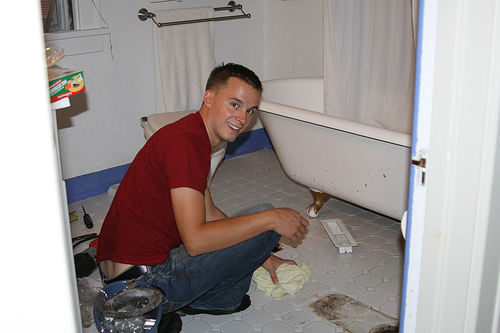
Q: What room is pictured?
A: It is a bathroom.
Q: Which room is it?
A: It is a bathroom.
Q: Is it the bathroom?
A: Yes, it is the bathroom.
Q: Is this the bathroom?
A: Yes, it is the bathroom.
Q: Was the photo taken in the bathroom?
A: Yes, it was taken in the bathroom.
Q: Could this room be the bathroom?
A: Yes, it is the bathroom.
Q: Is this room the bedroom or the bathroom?
A: It is the bathroom.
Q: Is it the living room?
A: No, it is the bathroom.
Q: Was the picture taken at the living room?
A: No, the picture was taken in the bathroom.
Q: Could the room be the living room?
A: No, it is the bathroom.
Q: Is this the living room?
A: No, it is the bathroom.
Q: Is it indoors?
A: Yes, it is indoors.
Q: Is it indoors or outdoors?
A: It is indoors.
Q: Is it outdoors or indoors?
A: It is indoors.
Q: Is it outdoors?
A: No, it is indoors.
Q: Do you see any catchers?
A: No, there are no catchers.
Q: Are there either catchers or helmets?
A: No, there are no catchers or helmets.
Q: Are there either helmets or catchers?
A: No, there are no catchers or helmets.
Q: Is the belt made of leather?
A: Yes, the belt is made of leather.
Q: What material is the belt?
A: The belt is made of leather.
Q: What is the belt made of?
A: The belt is made of leather.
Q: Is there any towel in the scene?
A: Yes, there is a towel.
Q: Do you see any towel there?
A: Yes, there is a towel.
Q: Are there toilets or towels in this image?
A: Yes, there is a towel.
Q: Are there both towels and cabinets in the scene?
A: No, there is a towel but no cabinets.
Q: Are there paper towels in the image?
A: No, there are no paper towels.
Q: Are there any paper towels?
A: No, there are no paper towels.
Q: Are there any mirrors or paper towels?
A: No, there are no paper towels or mirrors.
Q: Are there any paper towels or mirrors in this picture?
A: No, there are no paper towels or mirrors.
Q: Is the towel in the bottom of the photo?
A: Yes, the towel is in the bottom of the image.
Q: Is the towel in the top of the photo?
A: No, the towel is in the bottom of the image.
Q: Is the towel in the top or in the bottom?
A: The towel is in the bottom of the image.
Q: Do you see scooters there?
A: No, there are no scooters.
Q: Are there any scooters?
A: No, there are no scooters.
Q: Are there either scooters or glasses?
A: No, there are no scooters or glasses.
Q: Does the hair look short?
A: Yes, the hair is short.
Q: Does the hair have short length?
A: Yes, the hair is short.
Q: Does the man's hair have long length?
A: No, the hair is short.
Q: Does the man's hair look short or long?
A: The hair is short.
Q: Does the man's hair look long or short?
A: The hair is short.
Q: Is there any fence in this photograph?
A: No, there are no fences.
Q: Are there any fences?
A: No, there are no fences.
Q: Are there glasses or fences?
A: No, there are no fences or glasses.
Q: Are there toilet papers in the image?
A: No, there are no toilet papers.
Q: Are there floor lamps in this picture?
A: No, there are no floor lamps.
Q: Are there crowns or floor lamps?
A: No, there are no floor lamps or crowns.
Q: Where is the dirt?
A: The dirt is on the floor.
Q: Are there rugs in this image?
A: No, there are no rugs.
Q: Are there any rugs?
A: No, there are no rugs.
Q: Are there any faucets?
A: No, there are no faucets.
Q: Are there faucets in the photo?
A: No, there are no faucets.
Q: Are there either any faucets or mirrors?
A: No, there are no faucets or mirrors.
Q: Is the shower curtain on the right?
A: Yes, the shower curtain is on the right of the image.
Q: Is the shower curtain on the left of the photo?
A: No, the shower curtain is on the right of the image.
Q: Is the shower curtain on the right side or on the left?
A: The shower curtain is on the right of the image.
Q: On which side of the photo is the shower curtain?
A: The shower curtain is on the right of the image.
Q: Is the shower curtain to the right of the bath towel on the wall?
A: Yes, the shower curtain is to the right of the bath towel.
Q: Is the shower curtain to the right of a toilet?
A: No, the shower curtain is to the right of the bath towel.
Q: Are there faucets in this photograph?
A: No, there are no faucets.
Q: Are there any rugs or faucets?
A: No, there are no faucets or rugs.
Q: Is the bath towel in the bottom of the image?
A: No, the bath towel is in the top of the image.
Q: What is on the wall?
A: The bath towel is on the wall.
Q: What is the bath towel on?
A: The bath towel is on the wall.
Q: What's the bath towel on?
A: The bath towel is on the wall.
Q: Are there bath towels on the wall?
A: Yes, there is a bath towel on the wall.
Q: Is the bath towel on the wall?
A: Yes, the bath towel is on the wall.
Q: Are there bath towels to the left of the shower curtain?
A: Yes, there is a bath towel to the left of the shower curtain.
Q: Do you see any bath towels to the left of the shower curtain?
A: Yes, there is a bath towel to the left of the shower curtain.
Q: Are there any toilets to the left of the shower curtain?
A: No, there is a bath towel to the left of the shower curtain.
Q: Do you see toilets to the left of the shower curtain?
A: No, there is a bath towel to the left of the shower curtain.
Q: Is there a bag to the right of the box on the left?
A: No, there is a bath towel to the right of the box.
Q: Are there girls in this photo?
A: No, there are no girls.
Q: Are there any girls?
A: No, there are no girls.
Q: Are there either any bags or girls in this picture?
A: No, there are no girls or bags.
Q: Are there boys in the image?
A: No, there are no boys.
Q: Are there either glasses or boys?
A: No, there are no boys or glasses.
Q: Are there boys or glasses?
A: No, there are no boys or glasses.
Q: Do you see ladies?
A: No, there are no ladies.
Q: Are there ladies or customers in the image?
A: No, there are no ladies or customers.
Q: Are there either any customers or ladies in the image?
A: No, there are no ladies or customers.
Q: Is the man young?
A: Yes, the man is young.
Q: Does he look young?
A: Yes, the man is young.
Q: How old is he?
A: The man is young.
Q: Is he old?
A: No, the man is young.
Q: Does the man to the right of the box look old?
A: No, the man is young.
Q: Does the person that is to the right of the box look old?
A: No, the man is young.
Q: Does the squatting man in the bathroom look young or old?
A: The man is young.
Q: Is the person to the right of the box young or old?
A: The man is young.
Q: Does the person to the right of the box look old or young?
A: The man is young.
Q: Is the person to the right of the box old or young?
A: The man is young.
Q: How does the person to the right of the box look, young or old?
A: The man is young.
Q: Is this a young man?
A: Yes, this is a young man.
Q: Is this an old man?
A: No, this is a young man.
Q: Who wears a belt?
A: The man wears a belt.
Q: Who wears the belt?
A: The man wears a belt.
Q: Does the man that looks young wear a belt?
A: Yes, the man wears a belt.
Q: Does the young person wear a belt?
A: Yes, the man wears a belt.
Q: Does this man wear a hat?
A: No, the man wears a belt.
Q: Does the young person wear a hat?
A: No, the man wears a belt.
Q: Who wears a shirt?
A: The man wears a shirt.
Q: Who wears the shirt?
A: The man wears a shirt.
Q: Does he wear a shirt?
A: Yes, the man wears a shirt.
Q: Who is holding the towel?
A: The man is holding the towel.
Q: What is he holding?
A: The man is holding the towel.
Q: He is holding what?
A: The man is holding the towel.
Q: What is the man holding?
A: The man is holding the towel.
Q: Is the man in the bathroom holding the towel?
A: Yes, the man is holding the towel.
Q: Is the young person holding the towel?
A: Yes, the man is holding the towel.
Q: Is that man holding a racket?
A: No, the man is holding the towel.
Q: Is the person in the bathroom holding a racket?
A: No, the man is holding the towel.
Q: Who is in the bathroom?
A: The man is in the bathroom.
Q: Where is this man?
A: The man is in the bathroom.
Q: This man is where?
A: The man is in the bathroom.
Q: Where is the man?
A: The man is in the bathroom.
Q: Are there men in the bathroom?
A: Yes, there is a man in the bathroom.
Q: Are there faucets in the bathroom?
A: No, there is a man in the bathroom.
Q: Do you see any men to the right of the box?
A: Yes, there is a man to the right of the box.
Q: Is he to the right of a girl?
A: No, the man is to the right of the box.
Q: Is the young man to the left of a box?
A: No, the man is to the right of a box.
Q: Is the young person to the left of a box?
A: No, the man is to the right of a box.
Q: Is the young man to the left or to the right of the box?
A: The man is to the right of the box.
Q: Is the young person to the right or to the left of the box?
A: The man is to the right of the box.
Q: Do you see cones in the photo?
A: No, there are no cones.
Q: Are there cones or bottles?
A: No, there are no cones or bottles.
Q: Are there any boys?
A: No, there are no boys.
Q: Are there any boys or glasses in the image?
A: No, there are no boys or glasses.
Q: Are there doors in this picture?
A: Yes, there is a door.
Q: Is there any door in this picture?
A: Yes, there is a door.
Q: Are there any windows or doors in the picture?
A: Yes, there is a door.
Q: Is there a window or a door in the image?
A: Yes, there is a door.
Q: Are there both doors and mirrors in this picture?
A: No, there is a door but no mirrors.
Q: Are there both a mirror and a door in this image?
A: No, there is a door but no mirrors.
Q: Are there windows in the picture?
A: No, there are no windows.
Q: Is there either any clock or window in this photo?
A: No, there are no windows or clocks.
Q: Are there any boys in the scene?
A: No, there are no boys.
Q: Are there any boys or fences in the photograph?
A: No, there are no boys or fences.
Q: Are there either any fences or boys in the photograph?
A: No, there are no boys or fences.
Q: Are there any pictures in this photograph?
A: No, there are no pictures.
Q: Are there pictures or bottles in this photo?
A: No, there are no pictures or bottles.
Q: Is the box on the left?
A: Yes, the box is on the left of the image.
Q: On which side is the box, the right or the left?
A: The box is on the left of the image.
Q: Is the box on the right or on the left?
A: The box is on the left of the image.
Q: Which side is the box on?
A: The box is on the left of the image.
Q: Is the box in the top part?
A: Yes, the box is in the top of the image.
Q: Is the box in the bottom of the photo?
A: No, the box is in the top of the image.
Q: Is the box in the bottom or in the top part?
A: The box is in the top of the image.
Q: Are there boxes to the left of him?
A: Yes, there is a box to the left of the man.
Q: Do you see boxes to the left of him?
A: Yes, there is a box to the left of the man.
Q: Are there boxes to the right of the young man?
A: No, the box is to the left of the man.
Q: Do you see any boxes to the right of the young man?
A: No, the box is to the left of the man.